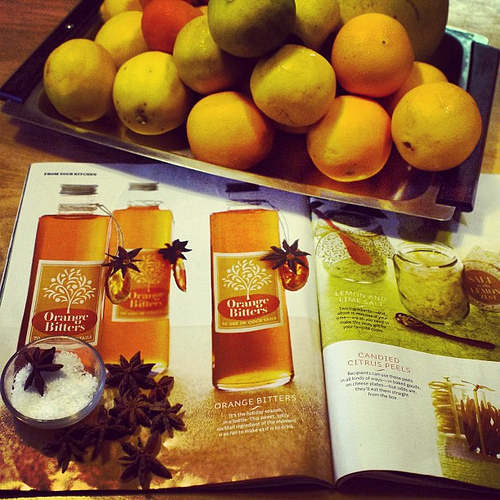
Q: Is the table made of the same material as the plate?
A: No, the table is made of wood and the plate is made of metal.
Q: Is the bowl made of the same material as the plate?
A: No, the bowl is made of glass and the plate is made of metal.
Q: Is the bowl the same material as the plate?
A: No, the bowl is made of glass and the plate is made of metal.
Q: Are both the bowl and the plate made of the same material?
A: No, the bowl is made of glass and the plate is made of metal.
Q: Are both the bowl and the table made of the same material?
A: No, the bowl is made of glass and the table is made of wood.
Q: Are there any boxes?
A: No, there are no boxes.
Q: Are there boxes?
A: No, there are no boxes.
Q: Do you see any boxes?
A: No, there are no boxes.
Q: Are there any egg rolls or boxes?
A: No, there are no boxes or egg rolls.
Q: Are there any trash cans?
A: No, there are no trash cans.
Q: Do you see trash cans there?
A: No, there are no trash cans.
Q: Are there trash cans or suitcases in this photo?
A: No, there are no trash cans or suitcases.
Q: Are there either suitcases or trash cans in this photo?
A: No, there are no trash cans or suitcases.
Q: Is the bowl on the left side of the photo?
A: Yes, the bowl is on the left of the image.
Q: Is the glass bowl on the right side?
A: No, the bowl is on the left of the image.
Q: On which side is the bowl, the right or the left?
A: The bowl is on the left of the image.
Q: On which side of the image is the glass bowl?
A: The bowl is on the left of the image.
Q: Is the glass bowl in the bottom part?
A: Yes, the bowl is in the bottom of the image.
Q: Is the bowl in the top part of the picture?
A: No, the bowl is in the bottom of the image.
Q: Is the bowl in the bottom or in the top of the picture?
A: The bowl is in the bottom of the image.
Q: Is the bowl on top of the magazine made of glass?
A: Yes, the bowl is made of glass.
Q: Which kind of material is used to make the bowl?
A: The bowl is made of glass.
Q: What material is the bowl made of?
A: The bowl is made of glass.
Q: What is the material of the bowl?
A: The bowl is made of glass.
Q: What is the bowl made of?
A: The bowl is made of glass.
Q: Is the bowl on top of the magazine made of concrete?
A: No, the bowl is made of glass.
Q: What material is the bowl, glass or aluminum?
A: The bowl is made of glass.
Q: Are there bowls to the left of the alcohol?
A: Yes, there is a bowl to the left of the alcohol.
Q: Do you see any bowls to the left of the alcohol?
A: Yes, there is a bowl to the left of the alcohol.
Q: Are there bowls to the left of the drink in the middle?
A: Yes, there is a bowl to the left of the alcohol.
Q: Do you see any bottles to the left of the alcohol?
A: No, there is a bowl to the left of the alcohol.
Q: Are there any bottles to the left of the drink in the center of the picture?
A: No, there is a bowl to the left of the alcohol.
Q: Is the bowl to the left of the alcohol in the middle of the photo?
A: Yes, the bowl is to the left of the alcohol.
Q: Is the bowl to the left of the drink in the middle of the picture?
A: Yes, the bowl is to the left of the alcohol.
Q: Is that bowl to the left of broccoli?
A: No, the bowl is to the left of the alcohol.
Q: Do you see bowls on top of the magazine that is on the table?
A: Yes, there is a bowl on top of the magazine.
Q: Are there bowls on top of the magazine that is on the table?
A: Yes, there is a bowl on top of the magazine.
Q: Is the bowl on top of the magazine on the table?
A: Yes, the bowl is on top of the magazine.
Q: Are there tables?
A: Yes, there is a table.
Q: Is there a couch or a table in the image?
A: Yes, there is a table.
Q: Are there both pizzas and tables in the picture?
A: No, there is a table but no pizzas.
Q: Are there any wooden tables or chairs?
A: Yes, there is a wood table.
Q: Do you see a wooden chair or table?
A: Yes, there is a wood table.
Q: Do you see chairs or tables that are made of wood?
A: Yes, the table is made of wood.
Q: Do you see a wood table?
A: Yes, there is a table that is made of wood.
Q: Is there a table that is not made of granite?
A: Yes, there is a table that is made of wood.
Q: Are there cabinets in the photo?
A: No, there are no cabinets.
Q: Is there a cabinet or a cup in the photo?
A: No, there are no cabinets or cups.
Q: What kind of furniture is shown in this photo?
A: The furniture is a table.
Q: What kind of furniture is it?
A: The piece of furniture is a table.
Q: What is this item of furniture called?
A: That is a table.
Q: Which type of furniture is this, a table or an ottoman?
A: That is a table.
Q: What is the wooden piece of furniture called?
A: The piece of furniture is a table.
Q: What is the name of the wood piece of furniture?
A: The piece of furniture is a table.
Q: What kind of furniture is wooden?
A: The furniture is a table.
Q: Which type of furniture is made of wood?
A: The furniture is a table.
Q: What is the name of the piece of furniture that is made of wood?
A: The piece of furniture is a table.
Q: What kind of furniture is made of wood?
A: The furniture is a table.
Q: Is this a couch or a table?
A: This is a table.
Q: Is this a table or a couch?
A: This is a table.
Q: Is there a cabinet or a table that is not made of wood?
A: No, there is a table but it is made of wood.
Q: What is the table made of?
A: The table is made of wood.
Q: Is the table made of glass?
A: No, the table is made of wood.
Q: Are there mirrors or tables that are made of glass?
A: No, there is a table but it is made of wood.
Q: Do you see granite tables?
A: No, there is a table but it is made of wood.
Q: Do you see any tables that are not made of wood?
A: No, there is a table but it is made of wood.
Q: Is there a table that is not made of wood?
A: No, there is a table but it is made of wood.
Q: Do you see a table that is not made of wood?
A: No, there is a table but it is made of wood.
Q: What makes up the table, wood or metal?
A: The table is made of wood.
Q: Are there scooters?
A: No, there are no scooters.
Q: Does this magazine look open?
A: Yes, the magazine is open.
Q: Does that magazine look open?
A: Yes, the magazine is open.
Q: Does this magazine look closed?
A: No, the magazine is open.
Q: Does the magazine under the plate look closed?
A: No, the magazine is open.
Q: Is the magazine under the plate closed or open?
A: The magazine is open.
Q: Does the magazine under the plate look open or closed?
A: The magazine is open.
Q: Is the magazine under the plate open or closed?
A: The magazine is open.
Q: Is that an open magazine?
A: Yes, that is an open magazine.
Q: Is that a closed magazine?
A: No, that is an open magazine.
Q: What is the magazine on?
A: The magazine is on the table.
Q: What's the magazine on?
A: The magazine is on the table.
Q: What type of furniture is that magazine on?
A: The magazine is on the table.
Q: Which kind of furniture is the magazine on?
A: The magazine is on the table.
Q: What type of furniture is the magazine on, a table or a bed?
A: The magazine is on a table.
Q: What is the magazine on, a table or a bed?
A: The magazine is on a table.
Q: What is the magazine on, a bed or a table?
A: The magazine is on a table.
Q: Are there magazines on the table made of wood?
A: Yes, there is a magazine on the table.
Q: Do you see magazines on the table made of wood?
A: Yes, there is a magazine on the table.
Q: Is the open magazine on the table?
A: Yes, the magazine is on the table.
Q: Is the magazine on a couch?
A: No, the magazine is on the table.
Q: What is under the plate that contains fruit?
A: The magazine is under the plate.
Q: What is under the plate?
A: The magazine is under the plate.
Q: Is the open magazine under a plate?
A: Yes, the magazine is under a plate.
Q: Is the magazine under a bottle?
A: No, the magazine is under a plate.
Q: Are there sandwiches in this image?
A: No, there are no sandwiches.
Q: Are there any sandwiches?
A: No, there are no sandwiches.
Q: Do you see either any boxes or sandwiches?
A: No, there are no sandwiches or boxes.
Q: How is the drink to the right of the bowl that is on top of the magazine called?
A: The drink is alcohol.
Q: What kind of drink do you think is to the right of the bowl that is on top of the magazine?
A: The drink is alcohol.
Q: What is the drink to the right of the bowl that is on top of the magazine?
A: The drink is alcohol.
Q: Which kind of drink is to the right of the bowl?
A: The drink is alcohol.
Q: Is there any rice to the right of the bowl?
A: No, there is alcohol to the right of the bowl.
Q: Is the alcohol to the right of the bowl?
A: Yes, the alcohol is to the right of the bowl.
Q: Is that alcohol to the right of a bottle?
A: No, the alcohol is to the right of the bowl.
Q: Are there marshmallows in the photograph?
A: No, there are no marshmallows.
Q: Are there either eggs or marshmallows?
A: No, there are no marshmallows or eggs.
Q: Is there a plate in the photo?
A: Yes, there is a plate.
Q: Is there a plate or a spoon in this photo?
A: Yes, there is a plate.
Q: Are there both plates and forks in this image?
A: No, there is a plate but no forks.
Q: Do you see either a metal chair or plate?
A: Yes, there is a metal plate.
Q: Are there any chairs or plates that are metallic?
A: Yes, the plate is metallic.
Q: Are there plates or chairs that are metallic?
A: Yes, the plate is metallic.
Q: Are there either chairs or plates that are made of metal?
A: Yes, the plate is made of metal.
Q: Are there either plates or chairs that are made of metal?
A: Yes, the plate is made of metal.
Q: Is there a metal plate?
A: Yes, there is a plate that is made of metal.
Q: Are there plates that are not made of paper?
A: Yes, there is a plate that is made of metal.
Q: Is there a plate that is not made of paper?
A: Yes, there is a plate that is made of metal.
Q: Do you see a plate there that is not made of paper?
A: Yes, there is a plate that is made of metal.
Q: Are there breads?
A: No, there are no breads.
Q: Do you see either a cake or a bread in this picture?
A: No, there are no breads or cakes.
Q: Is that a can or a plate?
A: That is a plate.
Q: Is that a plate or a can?
A: That is a plate.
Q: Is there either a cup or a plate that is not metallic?
A: No, there is a plate but it is metallic.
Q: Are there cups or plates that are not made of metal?
A: No, there is a plate but it is made of metal.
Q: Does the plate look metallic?
A: Yes, the plate is metallic.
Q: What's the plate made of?
A: The plate is made of metal.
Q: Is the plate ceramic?
A: No, the plate is metallic.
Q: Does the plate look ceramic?
A: No, the plate is metallic.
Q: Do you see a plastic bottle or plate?
A: No, there is a plate but it is metallic.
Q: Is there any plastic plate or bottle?
A: No, there is a plate but it is metallic.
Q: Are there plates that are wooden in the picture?
A: No, there is a plate but it is metallic.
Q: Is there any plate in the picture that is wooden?
A: No, there is a plate but it is metallic.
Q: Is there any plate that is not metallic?
A: No, there is a plate but it is metallic.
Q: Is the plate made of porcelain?
A: No, the plate is made of metal.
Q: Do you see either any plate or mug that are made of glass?
A: No, there is a plate but it is made of metal.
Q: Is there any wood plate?
A: No, there is a plate but it is made of metal.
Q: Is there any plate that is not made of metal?
A: No, there is a plate but it is made of metal.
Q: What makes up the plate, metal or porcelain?
A: The plate is made of metal.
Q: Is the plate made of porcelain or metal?
A: The plate is made of metal.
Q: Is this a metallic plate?
A: Yes, this is a metallic plate.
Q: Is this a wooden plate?
A: No, this is a metallic plate.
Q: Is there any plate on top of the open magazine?
A: Yes, there is a plate on top of the magazine.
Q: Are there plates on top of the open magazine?
A: Yes, there is a plate on top of the magazine.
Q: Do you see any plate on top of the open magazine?
A: Yes, there is a plate on top of the magazine.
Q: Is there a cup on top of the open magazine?
A: No, there is a plate on top of the magazine.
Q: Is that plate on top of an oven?
A: No, the plate is on top of the magazine.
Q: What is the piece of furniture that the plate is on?
A: The piece of furniture is a table.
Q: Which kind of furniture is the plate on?
A: The plate is on the table.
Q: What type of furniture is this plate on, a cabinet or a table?
A: The plate is on a table.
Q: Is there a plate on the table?
A: Yes, there is a plate on the table.